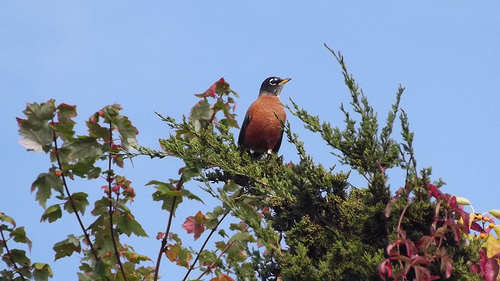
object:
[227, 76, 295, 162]
bird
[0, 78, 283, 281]
tree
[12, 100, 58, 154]
leaves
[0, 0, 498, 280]
sky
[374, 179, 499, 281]
sumac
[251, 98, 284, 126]
breast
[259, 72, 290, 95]
head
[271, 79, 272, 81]
markings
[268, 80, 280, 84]
eye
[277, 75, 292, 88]
beak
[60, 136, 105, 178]
leaf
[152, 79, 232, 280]
branch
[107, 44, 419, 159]
top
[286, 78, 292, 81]
tip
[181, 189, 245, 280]
branches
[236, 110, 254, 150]
wings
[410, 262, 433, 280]
foliage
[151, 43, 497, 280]
trees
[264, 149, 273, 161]
feet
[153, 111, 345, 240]
branch